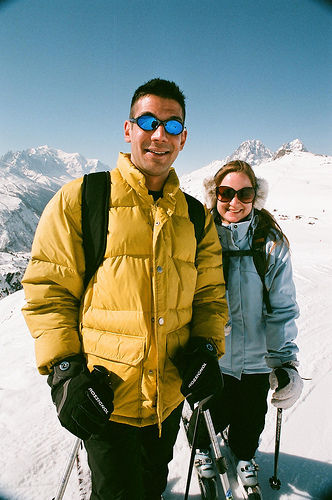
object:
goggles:
[131, 115, 185, 135]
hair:
[132, 76, 188, 103]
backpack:
[81, 169, 110, 267]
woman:
[187, 160, 304, 456]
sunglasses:
[215, 184, 256, 204]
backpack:
[250, 215, 271, 287]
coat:
[209, 209, 300, 381]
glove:
[267, 367, 305, 409]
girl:
[193, 159, 304, 500]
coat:
[22, 150, 231, 438]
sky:
[0, 0, 331, 150]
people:
[21, 77, 227, 499]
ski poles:
[268, 384, 283, 490]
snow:
[275, 154, 331, 228]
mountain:
[0, 143, 113, 185]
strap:
[183, 191, 206, 237]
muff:
[175, 345, 223, 406]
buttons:
[157, 265, 165, 327]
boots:
[194, 447, 258, 485]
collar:
[115, 152, 185, 200]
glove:
[43, 360, 115, 438]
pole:
[51, 436, 83, 500]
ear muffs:
[203, 178, 217, 208]